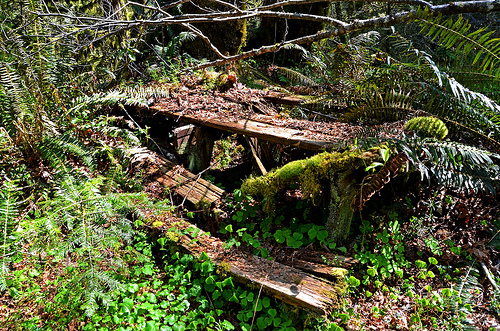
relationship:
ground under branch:
[0, 158, 498, 330] [25, 0, 499, 73]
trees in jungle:
[0, 2, 500, 180] [1, 2, 499, 330]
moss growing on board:
[243, 149, 364, 193] [76, 72, 413, 158]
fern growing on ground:
[0, 31, 162, 180] [0, 158, 498, 330]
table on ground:
[76, 73, 415, 313] [0, 158, 498, 330]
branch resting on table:
[25, 0, 499, 73] [76, 73, 415, 313]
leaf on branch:
[409, 7, 500, 78] [25, 0, 499, 73]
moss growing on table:
[243, 149, 364, 193] [76, 73, 415, 313]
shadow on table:
[207, 214, 318, 285] [76, 73, 415, 313]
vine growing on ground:
[202, 250, 290, 331] [0, 158, 498, 330]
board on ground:
[76, 72, 413, 158] [0, 158, 498, 330]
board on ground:
[85, 141, 363, 317] [0, 158, 498, 330]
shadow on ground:
[207, 214, 318, 285] [0, 158, 498, 330]